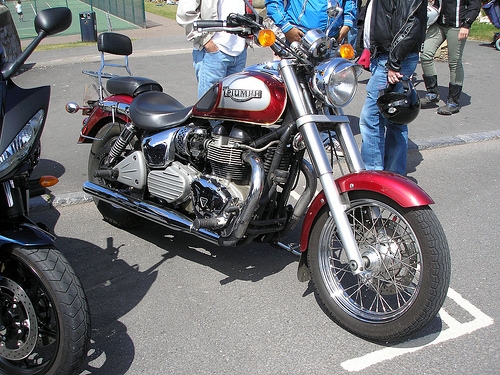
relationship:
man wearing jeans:
[355, 0, 425, 176] [359, 52, 418, 178]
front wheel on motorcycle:
[306, 190, 451, 341] [64, 2, 450, 341]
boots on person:
[418, 74, 463, 116] [420, 1, 482, 115]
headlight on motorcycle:
[328, 60, 364, 107] [64, 2, 450, 341]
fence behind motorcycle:
[1, 0, 148, 40] [64, 2, 450, 341]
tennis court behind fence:
[3, 1, 144, 45] [1, 0, 148, 40]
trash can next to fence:
[79, 12, 100, 43] [1, 0, 148, 40]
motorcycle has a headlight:
[64, 2, 450, 341] [328, 60, 364, 107]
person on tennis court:
[14, 0, 24, 22] [3, 1, 144, 45]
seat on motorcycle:
[106, 75, 195, 130] [64, 2, 450, 341]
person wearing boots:
[420, 1, 482, 115] [418, 74, 463, 116]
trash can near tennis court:
[79, 12, 100, 43] [3, 1, 144, 45]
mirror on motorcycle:
[34, 7, 72, 36] [0, 7, 92, 373]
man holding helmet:
[355, 0, 425, 176] [376, 74, 420, 127]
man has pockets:
[175, 0, 252, 102] [203, 47, 247, 63]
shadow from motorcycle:
[103, 206, 442, 349] [64, 2, 450, 341]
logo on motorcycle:
[222, 85, 262, 103] [64, 2, 450, 341]